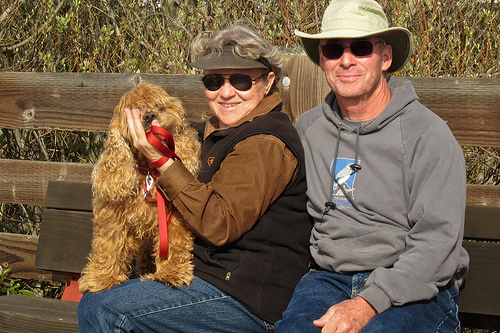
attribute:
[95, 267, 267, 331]
jeans — blue 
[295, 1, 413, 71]
hat — beige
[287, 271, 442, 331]
blue jeans — blue 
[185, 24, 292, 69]
hair — gray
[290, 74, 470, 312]
sweatshirt — gray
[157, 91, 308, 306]
vest — black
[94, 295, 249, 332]
jeans — blue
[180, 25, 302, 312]
woman — sitting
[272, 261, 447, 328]
jeans — blue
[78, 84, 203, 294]
dog — golden, gold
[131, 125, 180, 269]
leash — red